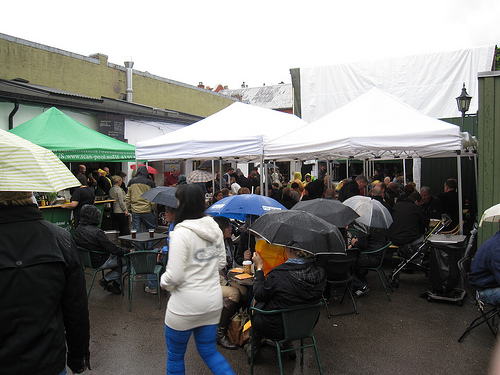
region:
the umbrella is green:
[50, 124, 81, 136]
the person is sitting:
[79, 231, 105, 273]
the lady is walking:
[166, 182, 231, 365]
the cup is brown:
[238, 256, 253, 279]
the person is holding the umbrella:
[212, 192, 282, 259]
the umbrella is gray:
[358, 197, 378, 217]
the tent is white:
[356, 112, 396, 135]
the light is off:
[446, 74, 474, 115]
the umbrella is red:
[133, 162, 155, 173]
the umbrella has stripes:
[8, 139, 51, 177]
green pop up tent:
[13, 107, 133, 162]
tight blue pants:
[165, 323, 232, 373]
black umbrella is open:
[252, 210, 348, 257]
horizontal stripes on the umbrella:
[0, 128, 83, 190]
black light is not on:
[456, 83, 477, 133]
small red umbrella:
[130, 162, 159, 177]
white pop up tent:
[266, 88, 465, 153]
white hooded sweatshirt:
[162, 217, 227, 330]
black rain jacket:
[0, 208, 87, 371]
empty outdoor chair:
[125, 248, 165, 303]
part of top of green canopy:
[8, 103, 138, 163]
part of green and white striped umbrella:
[0, 127, 83, 194]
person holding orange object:
[253, 235, 286, 277]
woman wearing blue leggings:
[158, 183, 235, 373]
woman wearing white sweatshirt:
[154, 183, 239, 373]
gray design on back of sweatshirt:
[193, 240, 223, 262]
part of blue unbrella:
[203, 191, 286, 216]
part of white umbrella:
[346, 194, 393, 228]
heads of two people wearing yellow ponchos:
[290, 168, 313, 183]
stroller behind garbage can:
[386, 208, 469, 307]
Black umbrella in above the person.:
[248, 208, 352, 257]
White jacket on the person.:
[160, 183, 231, 330]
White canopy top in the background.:
[266, 86, 471, 161]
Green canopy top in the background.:
[12, 106, 139, 161]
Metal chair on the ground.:
[245, 299, 324, 372]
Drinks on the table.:
[125, 226, 156, 240]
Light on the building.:
[450, 79, 477, 127]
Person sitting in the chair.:
[240, 233, 330, 369]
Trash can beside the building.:
[420, 229, 469, 304]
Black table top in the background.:
[118, 229, 167, 249]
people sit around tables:
[48, 158, 471, 359]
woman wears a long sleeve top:
[147, 178, 251, 373]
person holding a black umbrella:
[239, 206, 353, 316]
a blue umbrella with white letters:
[201, 191, 289, 222]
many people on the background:
[239, 168, 411, 201]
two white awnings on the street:
[130, 81, 461, 176]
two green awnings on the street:
[15, 100, 135, 170]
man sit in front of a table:
[63, 195, 163, 273]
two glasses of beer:
[125, 220, 159, 241]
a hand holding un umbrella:
[224, 203, 254, 267]